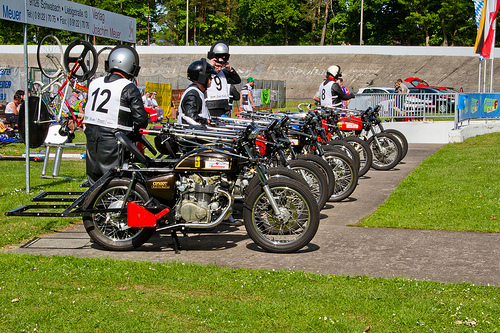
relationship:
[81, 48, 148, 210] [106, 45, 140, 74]
man has helmet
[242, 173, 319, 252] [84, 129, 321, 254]
tire on motorcycle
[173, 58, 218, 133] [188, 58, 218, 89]
man has helmet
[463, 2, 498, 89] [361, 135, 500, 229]
flags are behind grass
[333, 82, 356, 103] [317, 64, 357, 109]
arm of a man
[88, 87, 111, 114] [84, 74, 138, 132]
number on vest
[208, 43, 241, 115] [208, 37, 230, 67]
people removing helmet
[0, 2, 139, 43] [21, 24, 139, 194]
sign on poles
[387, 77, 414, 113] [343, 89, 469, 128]
people behind fence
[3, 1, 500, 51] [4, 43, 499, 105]
trees behind wall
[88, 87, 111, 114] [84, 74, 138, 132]
number on a vest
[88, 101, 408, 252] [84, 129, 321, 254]
motorcycles in a row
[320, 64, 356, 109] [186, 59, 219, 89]
man wearing helmet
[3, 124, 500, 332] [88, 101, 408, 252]
grass by motorcycles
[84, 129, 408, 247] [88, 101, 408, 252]
wheels on bikes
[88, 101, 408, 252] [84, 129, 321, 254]
bikes in a row